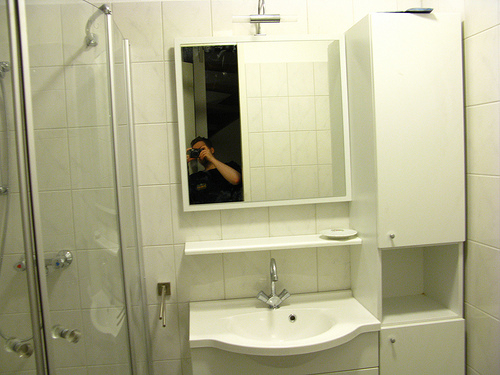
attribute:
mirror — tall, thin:
[169, 38, 251, 206]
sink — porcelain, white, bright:
[188, 304, 370, 347]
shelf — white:
[174, 232, 365, 258]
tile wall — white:
[131, 47, 166, 118]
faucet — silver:
[248, 256, 294, 310]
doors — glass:
[19, 12, 117, 164]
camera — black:
[188, 146, 201, 158]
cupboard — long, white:
[360, 14, 472, 246]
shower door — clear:
[39, 225, 108, 310]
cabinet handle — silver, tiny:
[381, 230, 399, 243]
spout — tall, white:
[272, 275, 282, 282]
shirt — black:
[190, 172, 221, 203]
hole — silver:
[289, 314, 297, 323]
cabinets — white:
[377, 215, 460, 353]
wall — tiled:
[243, 60, 325, 193]